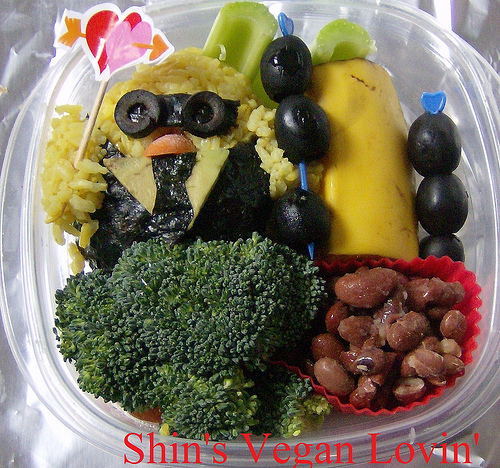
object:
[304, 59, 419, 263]
banana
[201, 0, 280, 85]
celery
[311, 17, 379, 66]
celery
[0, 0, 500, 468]
bowl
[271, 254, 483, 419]
wrapper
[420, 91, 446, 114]
toothpicks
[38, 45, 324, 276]
rice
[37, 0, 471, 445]
food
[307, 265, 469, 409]
beans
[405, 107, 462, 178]
olive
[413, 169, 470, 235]
olive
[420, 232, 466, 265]
olive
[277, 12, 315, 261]
blue toothpick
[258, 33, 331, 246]
black olives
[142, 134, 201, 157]
slice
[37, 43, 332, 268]
penguin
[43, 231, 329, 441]
broccoli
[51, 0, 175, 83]
sticker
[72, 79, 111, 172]
toothpick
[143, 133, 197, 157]
carrot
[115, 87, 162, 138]
olive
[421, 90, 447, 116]
heart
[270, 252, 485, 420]
cup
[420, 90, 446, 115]
blue heart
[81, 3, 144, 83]
heart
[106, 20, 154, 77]
heart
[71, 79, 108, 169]
stick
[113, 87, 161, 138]
slice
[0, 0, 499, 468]
dish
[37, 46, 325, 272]
bird